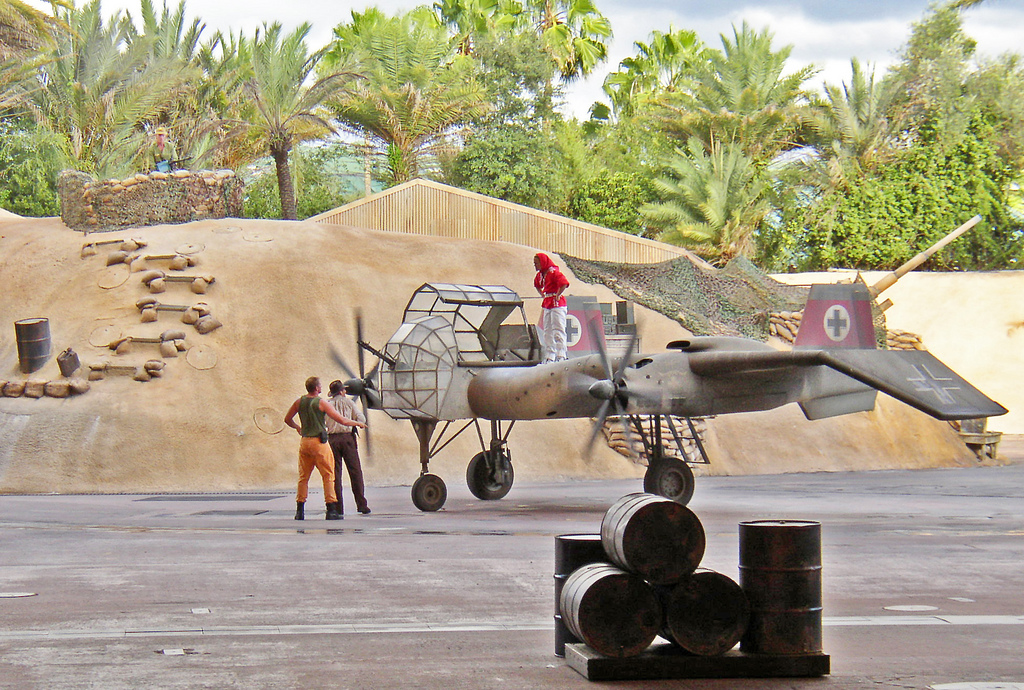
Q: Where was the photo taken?
A: Near the old airplane.